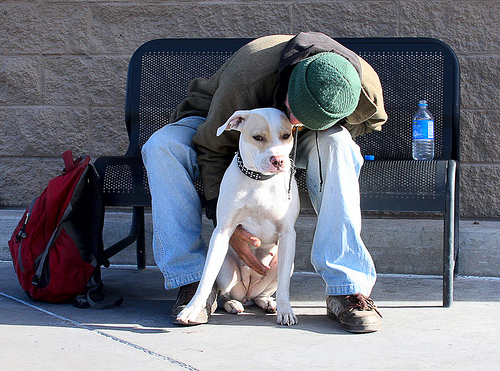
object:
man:
[140, 30, 387, 332]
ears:
[215, 110, 249, 136]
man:
[121, 33, 456, 315]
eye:
[252, 135, 265, 142]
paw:
[175, 298, 205, 326]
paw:
[275, 296, 299, 327]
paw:
[222, 297, 247, 315]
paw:
[256, 296, 279, 314]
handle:
[62, 150, 77, 173]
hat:
[287, 52, 361, 130]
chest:
[218, 183, 298, 218]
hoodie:
[168, 32, 390, 216]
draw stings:
[288, 125, 298, 200]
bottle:
[412, 100, 435, 161]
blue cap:
[364, 155, 375, 162]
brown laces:
[344, 294, 383, 318]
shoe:
[325, 295, 383, 332]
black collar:
[237, 148, 281, 182]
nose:
[269, 147, 284, 167]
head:
[216, 107, 297, 181]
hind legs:
[214, 252, 254, 315]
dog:
[175, 107, 300, 327]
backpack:
[7, 143, 125, 310]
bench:
[87, 37, 457, 309]